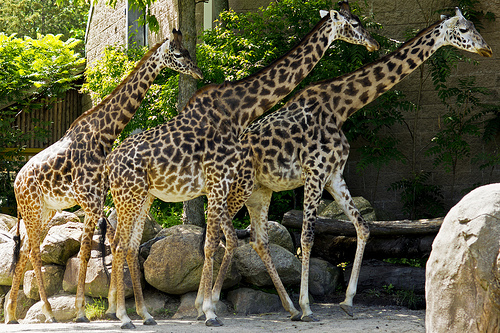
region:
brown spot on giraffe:
[272, 126, 289, 140]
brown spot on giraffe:
[405, 56, 417, 70]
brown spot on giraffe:
[387, 61, 397, 72]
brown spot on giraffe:
[51, 157, 65, 169]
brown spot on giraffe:
[219, 95, 244, 112]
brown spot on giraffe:
[280, 141, 297, 155]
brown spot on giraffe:
[273, 82, 290, 95]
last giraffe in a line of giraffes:
[4, 32, 211, 331]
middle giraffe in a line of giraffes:
[85, 4, 381, 330]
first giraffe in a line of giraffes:
[207, 2, 496, 331]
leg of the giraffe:
[106, 255, 136, 323]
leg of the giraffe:
[294, 215, 314, 316]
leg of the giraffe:
[340, 217, 360, 319]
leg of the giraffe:
[297, 187, 322, 320]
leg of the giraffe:
[243, 245, 299, 320]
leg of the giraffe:
[210, 237, 245, 299]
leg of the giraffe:
[75, 238, 97, 311]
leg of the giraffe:
[23, 243, 60, 322]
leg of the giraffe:
[8, 248, 25, 329]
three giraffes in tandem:
[4, 7, 485, 324]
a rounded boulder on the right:
[425, 180, 497, 331]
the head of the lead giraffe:
[439, 7, 494, 59]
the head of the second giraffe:
[314, 4, 384, 54]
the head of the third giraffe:
[157, 29, 204, 80]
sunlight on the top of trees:
[0, 33, 89, 105]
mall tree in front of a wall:
[78, 43, 149, 107]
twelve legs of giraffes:
[4, 174, 370, 327]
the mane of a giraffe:
[331, 9, 456, 86]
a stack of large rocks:
[0, 207, 332, 320]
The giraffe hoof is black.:
[203, 314, 223, 325]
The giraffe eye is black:
[459, 26, 467, 36]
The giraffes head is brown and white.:
[436, 6, 493, 62]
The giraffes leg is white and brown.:
[343, 226, 373, 326]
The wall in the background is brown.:
[418, 89, 496, 179]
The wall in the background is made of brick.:
[410, 85, 496, 174]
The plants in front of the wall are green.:
[426, 86, 496, 174]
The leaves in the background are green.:
[1, 37, 86, 86]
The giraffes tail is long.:
[98, 160, 109, 282]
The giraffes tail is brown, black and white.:
[98, 160, 108, 276]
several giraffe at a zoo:
[2, 2, 487, 329]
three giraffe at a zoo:
[10, 6, 492, 328]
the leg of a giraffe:
[331, 178, 377, 321]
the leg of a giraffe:
[300, 182, 320, 323]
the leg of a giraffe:
[256, 203, 298, 323]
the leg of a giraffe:
[196, 193, 220, 328]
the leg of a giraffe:
[29, 239, 59, 327]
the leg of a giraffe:
[4, 253, 24, 328]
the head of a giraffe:
[427, 3, 494, 73]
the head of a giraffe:
[310, 1, 379, 57]